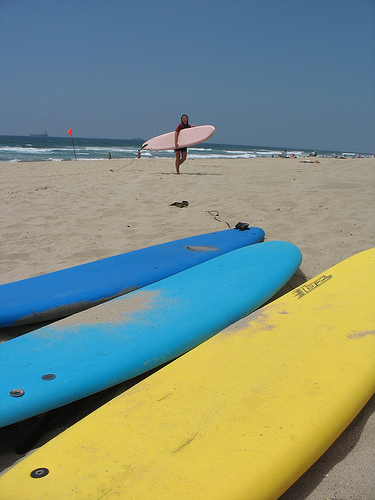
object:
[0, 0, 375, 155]
sky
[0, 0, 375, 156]
clouds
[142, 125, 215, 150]
surfboard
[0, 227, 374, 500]
laying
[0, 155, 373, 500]
beach.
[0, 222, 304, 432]
two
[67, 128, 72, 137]
orange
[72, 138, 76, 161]
stick.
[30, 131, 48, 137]
boat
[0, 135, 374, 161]
horizon.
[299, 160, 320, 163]
laying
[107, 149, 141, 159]
two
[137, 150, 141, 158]
walking.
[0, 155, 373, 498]
sand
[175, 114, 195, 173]
surfer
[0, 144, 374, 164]
waves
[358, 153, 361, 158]
sitting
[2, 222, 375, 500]
three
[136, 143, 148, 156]
black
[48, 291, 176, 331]
sand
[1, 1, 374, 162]
wind.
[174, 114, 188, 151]
black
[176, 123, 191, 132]
red.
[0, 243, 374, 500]
plain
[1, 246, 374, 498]
surfboard.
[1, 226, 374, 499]
row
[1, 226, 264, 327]
bright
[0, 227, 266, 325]
dark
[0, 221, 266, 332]
surfboard.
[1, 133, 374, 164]
turbluent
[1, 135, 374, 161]
water.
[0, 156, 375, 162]
edge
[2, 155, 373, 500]
beige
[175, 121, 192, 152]
swimsuit.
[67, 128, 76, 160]
flag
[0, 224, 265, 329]
light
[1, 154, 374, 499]
brown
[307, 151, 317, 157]
sitting